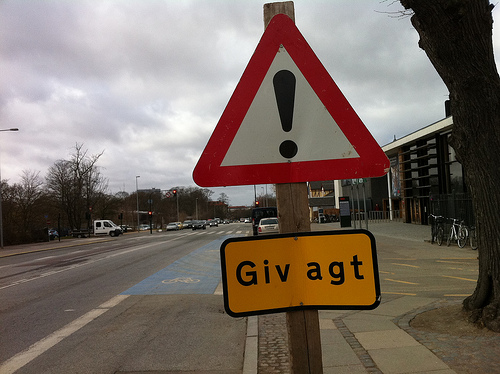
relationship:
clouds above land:
[53, 20, 187, 122] [3, 207, 273, 369]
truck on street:
[65, 218, 122, 238] [66, 236, 213, 355]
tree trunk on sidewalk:
[396, 0, 498, 330] [298, 215, 498, 371]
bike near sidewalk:
[427, 211, 449, 248] [240, 207, 499, 372]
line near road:
[4, 291, 157, 372] [0, 202, 241, 372]